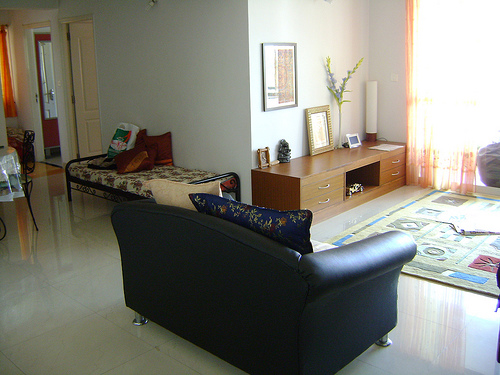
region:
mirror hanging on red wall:
[34, 36, 61, 135]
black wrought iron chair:
[10, 121, 45, 236]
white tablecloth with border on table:
[2, 142, 27, 223]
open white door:
[63, 25, 110, 170]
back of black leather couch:
[105, 203, 408, 367]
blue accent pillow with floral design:
[191, 184, 322, 257]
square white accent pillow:
[143, 166, 239, 213]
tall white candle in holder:
[362, 75, 382, 147]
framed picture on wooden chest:
[298, 95, 340, 161]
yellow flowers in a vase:
[320, 51, 368, 154]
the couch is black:
[206, 257, 373, 354]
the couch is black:
[243, 263, 318, 367]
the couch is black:
[264, 303, 323, 363]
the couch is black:
[290, 228, 337, 325]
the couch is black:
[254, 273, 291, 354]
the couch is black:
[276, 327, 306, 359]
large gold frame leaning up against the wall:
[299, 101, 341, 161]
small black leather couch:
[99, 158, 416, 374]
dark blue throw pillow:
[186, 183, 329, 263]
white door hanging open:
[67, 21, 121, 160]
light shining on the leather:
[315, 243, 413, 272]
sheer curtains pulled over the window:
[393, 6, 484, 194]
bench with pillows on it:
[55, 124, 242, 230]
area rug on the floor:
[323, 178, 498, 313]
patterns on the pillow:
[199, 201, 298, 234]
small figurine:
[276, 140, 293, 162]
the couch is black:
[211, 220, 300, 359]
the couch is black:
[293, 322, 313, 350]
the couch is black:
[265, 260, 310, 326]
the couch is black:
[162, 163, 317, 360]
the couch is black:
[219, 122, 336, 366]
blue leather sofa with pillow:
[101, 179, 410, 359]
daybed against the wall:
[66, 140, 236, 213]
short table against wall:
[259, 123, 409, 217]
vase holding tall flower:
[313, 52, 358, 157]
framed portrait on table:
[304, 97, 342, 163]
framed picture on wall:
[254, 33, 308, 123]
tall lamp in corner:
[358, 75, 386, 150]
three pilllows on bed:
[111, 127, 182, 182]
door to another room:
[54, 14, 108, 195]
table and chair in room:
[3, 131, 50, 235]